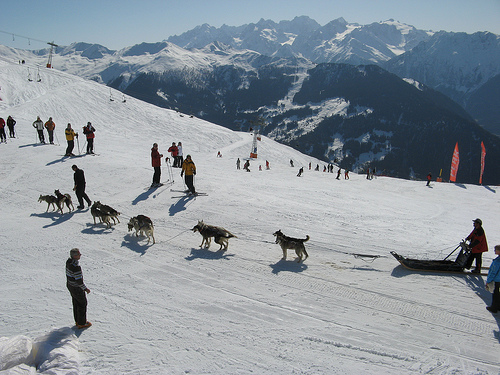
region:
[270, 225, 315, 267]
two dogs pulling a sled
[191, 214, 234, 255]
two dogs pulling a sled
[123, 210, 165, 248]
two dogs pulling a sled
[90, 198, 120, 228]
two dogs pulling a sled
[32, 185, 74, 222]
two dogs pulling a sled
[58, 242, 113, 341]
a man standing on snow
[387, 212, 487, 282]
a man riding a sled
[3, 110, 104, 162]
several people on skis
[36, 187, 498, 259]
several dogs pulling a sled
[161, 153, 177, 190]
two ski poles in the snow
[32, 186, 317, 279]
the dogs for the sled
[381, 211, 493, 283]
the man on the dog sled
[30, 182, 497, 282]
the train of dogs for the sled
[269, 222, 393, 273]
the straps and ropes connecting the dogs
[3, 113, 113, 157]
the people gather to watch the dogs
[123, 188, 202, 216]
the shadow of the people on the snow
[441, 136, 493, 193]
the orange flags waving in the wind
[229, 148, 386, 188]
people skiing on the mountain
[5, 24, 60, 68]
the chair lift for the mountain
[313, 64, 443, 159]
the rocky tree covered mountains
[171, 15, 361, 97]
mountains beyond the ski slope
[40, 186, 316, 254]
dogs on a dog sled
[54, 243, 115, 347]
person watching the dog sled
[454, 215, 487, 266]
person riding the dog sled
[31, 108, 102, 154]
people standing at the top of the ski slope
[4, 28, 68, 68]
ski lift in the distance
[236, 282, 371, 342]
tracks in the snow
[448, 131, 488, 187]
flags on the slope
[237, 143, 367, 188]
people going down the slope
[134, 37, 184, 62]
snow on the mountain top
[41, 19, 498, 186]
mountains are around the area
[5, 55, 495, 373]
snow is covering the ground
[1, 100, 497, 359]
people are standing around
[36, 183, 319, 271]
animals are in a group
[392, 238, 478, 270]
a sled being used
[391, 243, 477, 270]
the sled is a dark color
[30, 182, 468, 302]
the animals are pulling the sled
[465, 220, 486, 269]
the person has a red jacket on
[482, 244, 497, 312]
the person has a blue jacket on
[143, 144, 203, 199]
people are going skiing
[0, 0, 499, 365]
people on top of mountain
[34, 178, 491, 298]
person driving dog sled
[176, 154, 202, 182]
person wearing yellow jacket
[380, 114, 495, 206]
red flags on side of mountain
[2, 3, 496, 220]
addition mountains in background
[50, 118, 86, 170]
person holding ski poles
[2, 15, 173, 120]
ski lift in background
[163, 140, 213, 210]
person standing on skis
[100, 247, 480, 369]
long tracks in snow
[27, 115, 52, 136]
person wearing white top